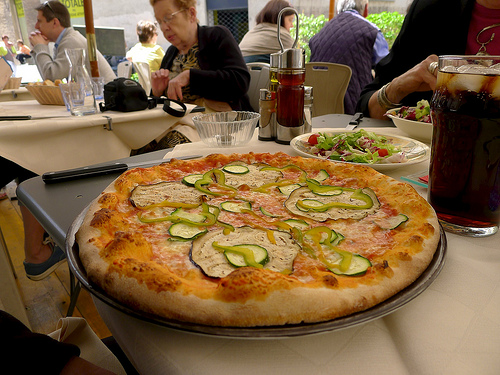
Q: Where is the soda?
A: In the glass.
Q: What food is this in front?
A: Pizza.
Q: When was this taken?
A: Daytime.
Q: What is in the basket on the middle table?
A: Bread.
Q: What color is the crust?
A: Brown.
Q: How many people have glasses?
A: 2.